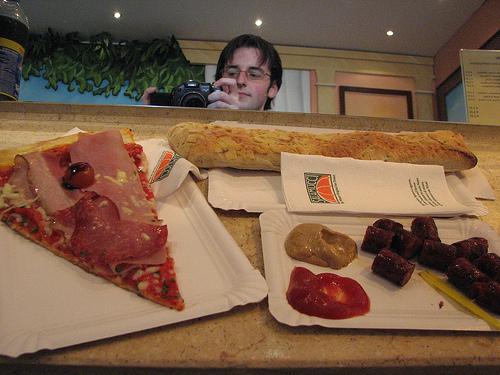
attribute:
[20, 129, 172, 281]
toppings — meaty 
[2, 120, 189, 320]
pizza — little, large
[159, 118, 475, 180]
bread — long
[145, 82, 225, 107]
camera — black 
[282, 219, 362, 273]
mustard — small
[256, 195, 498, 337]
plate — white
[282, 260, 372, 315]
dipping sauce — red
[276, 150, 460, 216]
napkin — white 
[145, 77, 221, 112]
camera — black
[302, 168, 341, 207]
logo — green, orange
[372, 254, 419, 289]
food — chopped , brown 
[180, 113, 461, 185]
yellow fork — plastic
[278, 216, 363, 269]
mustard — yellow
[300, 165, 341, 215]
logo — orange, green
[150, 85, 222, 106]
camera — black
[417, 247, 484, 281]
sausage — brown